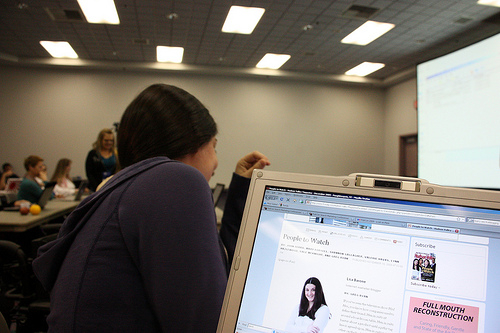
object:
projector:
[416, 33, 499, 190]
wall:
[382, 32, 500, 176]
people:
[29, 83, 269, 333]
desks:
[0, 196, 96, 232]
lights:
[39, 0, 395, 77]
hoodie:
[32, 156, 227, 333]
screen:
[232, 185, 498, 332]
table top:
[0, 195, 89, 231]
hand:
[235, 151, 271, 178]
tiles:
[0, 0, 500, 80]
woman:
[287, 277, 332, 333]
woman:
[85, 128, 121, 192]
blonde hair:
[92, 128, 114, 151]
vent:
[349, 4, 380, 18]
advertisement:
[406, 296, 479, 333]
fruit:
[20, 200, 42, 215]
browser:
[265, 189, 304, 204]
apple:
[30, 204, 41, 215]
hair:
[117, 83, 217, 170]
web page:
[245, 186, 500, 331]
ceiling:
[0, 0, 500, 88]